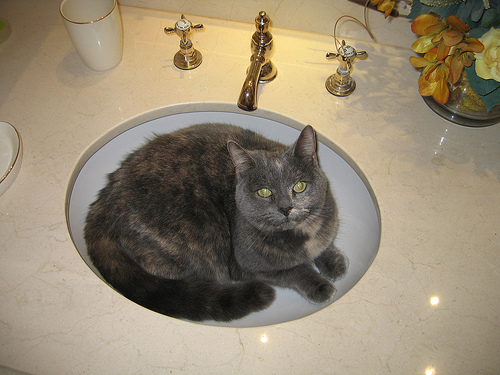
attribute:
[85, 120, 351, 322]
cat — grey, brown, present, looking, gray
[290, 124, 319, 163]
ear — pointed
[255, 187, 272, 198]
eye — green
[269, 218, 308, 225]
mouth — closed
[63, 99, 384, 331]
sink — round, white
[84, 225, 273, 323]
tail — long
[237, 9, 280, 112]
faucet — gold, shiny, metalic, off, present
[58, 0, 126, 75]
glass — gold rimmed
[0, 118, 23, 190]
dish — gold rimmed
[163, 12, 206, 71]
handle — cold